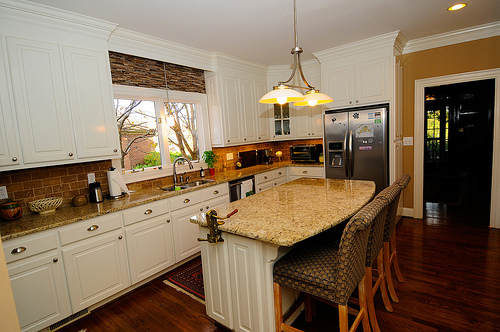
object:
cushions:
[274, 246, 340, 291]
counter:
[188, 176, 375, 248]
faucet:
[172, 157, 193, 184]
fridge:
[349, 105, 390, 192]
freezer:
[322, 112, 349, 179]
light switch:
[403, 137, 414, 146]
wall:
[398, 24, 500, 218]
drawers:
[202, 185, 231, 202]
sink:
[158, 180, 209, 192]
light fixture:
[446, 3, 466, 12]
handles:
[343, 129, 355, 177]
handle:
[87, 225, 98, 231]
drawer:
[56, 214, 122, 246]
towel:
[240, 179, 253, 199]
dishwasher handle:
[229, 176, 256, 203]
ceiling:
[23, 0, 500, 67]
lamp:
[256, 0, 335, 108]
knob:
[118, 236, 122, 240]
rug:
[160, 261, 204, 305]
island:
[187, 176, 375, 332]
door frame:
[413, 67, 500, 230]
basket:
[28, 196, 63, 216]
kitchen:
[0, 0, 500, 332]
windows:
[160, 102, 207, 165]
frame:
[112, 86, 215, 184]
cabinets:
[0, 3, 121, 170]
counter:
[0, 177, 223, 243]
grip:
[197, 209, 238, 244]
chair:
[366, 185, 401, 332]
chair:
[379, 173, 410, 303]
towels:
[106, 171, 129, 197]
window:
[109, 97, 162, 174]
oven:
[290, 144, 323, 164]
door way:
[412, 66, 494, 230]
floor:
[40, 217, 500, 332]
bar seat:
[273, 203, 375, 332]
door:
[3, 36, 77, 164]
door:
[4, 254, 72, 330]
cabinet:
[1, 182, 228, 332]